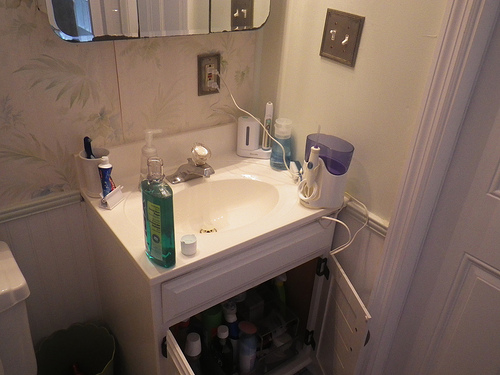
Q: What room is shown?
A: It is a bathroom.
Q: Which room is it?
A: It is a bathroom.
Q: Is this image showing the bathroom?
A: Yes, it is showing the bathroom.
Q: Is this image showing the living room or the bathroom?
A: It is showing the bathroom.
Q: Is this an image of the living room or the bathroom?
A: It is showing the bathroom.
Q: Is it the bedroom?
A: No, it is the bathroom.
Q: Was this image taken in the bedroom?
A: No, the picture was taken in the bathroom.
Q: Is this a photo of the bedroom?
A: No, the picture is showing the bathroom.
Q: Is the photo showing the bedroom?
A: No, the picture is showing the bathroom.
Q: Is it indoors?
A: Yes, it is indoors.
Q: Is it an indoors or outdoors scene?
A: It is indoors.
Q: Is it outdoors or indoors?
A: It is indoors.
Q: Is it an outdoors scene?
A: No, it is indoors.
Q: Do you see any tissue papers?
A: No, there are no tissue papers.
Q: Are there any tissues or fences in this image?
A: No, there are no tissues or fences.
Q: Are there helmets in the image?
A: No, there are no helmets.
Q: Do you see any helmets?
A: No, there are no helmets.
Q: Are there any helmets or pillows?
A: No, there are no helmets or pillows.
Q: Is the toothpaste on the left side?
A: Yes, the toothpaste is on the left of the image.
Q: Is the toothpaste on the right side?
A: No, the toothpaste is on the left of the image.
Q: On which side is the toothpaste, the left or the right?
A: The toothpaste is on the left of the image.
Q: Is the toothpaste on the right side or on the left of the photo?
A: The toothpaste is on the left of the image.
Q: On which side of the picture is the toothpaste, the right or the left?
A: The toothpaste is on the left of the image.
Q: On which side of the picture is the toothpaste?
A: The toothpaste is on the left of the image.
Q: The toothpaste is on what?
A: The toothpaste is on the sink.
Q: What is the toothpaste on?
A: The toothpaste is on the sink.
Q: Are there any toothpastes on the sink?
A: Yes, there is a toothpaste on the sink.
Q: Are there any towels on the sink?
A: No, there is a toothpaste on the sink.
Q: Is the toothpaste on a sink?
A: Yes, the toothpaste is on a sink.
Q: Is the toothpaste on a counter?
A: No, the toothpaste is on a sink.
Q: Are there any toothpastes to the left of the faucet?
A: Yes, there is a toothpaste to the left of the faucet.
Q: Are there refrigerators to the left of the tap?
A: No, there is a toothpaste to the left of the tap.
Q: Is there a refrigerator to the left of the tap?
A: No, there is a toothpaste to the left of the tap.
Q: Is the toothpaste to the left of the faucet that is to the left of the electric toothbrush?
A: Yes, the toothpaste is to the left of the tap.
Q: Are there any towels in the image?
A: No, there are no towels.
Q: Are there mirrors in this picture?
A: Yes, there is a mirror.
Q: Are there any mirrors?
A: Yes, there is a mirror.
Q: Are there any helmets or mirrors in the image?
A: Yes, there is a mirror.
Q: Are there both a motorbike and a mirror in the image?
A: No, there is a mirror but no motorcycles.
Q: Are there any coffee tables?
A: No, there are no coffee tables.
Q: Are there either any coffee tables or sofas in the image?
A: No, there are no coffee tables or sofas.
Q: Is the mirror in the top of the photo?
A: Yes, the mirror is in the top of the image.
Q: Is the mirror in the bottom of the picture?
A: No, the mirror is in the top of the image.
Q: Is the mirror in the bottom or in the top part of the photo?
A: The mirror is in the top of the image.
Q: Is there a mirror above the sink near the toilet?
A: Yes, there is a mirror above the sink.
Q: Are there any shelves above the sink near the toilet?
A: No, there is a mirror above the sink.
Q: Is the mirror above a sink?
A: Yes, the mirror is above a sink.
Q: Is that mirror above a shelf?
A: No, the mirror is above a sink.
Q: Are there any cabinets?
A: Yes, there is a cabinet.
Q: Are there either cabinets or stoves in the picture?
A: Yes, there is a cabinet.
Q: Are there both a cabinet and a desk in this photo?
A: No, there is a cabinet but no desks.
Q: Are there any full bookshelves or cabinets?
A: Yes, there is a full cabinet.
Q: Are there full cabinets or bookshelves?
A: Yes, there is a full cabinet.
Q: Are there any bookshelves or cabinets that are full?
A: Yes, the cabinet is full.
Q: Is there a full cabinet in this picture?
A: Yes, there is a full cabinet.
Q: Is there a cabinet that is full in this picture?
A: Yes, there is a full cabinet.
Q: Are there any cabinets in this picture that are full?
A: Yes, there is a cabinet that is full.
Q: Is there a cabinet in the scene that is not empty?
A: Yes, there is an full cabinet.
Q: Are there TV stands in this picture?
A: No, there are no TV stands.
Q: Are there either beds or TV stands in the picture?
A: No, there are no TV stands or beds.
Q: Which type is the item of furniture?
A: The piece of furniture is a cabinet.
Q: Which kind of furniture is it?
A: The piece of furniture is a cabinet.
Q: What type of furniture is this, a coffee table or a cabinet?
A: This is a cabinet.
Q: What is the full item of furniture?
A: The piece of furniture is a cabinet.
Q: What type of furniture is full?
A: The furniture is a cabinet.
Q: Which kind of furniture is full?
A: The furniture is a cabinet.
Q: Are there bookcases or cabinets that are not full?
A: No, there is a cabinet but it is full.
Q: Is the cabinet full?
A: Yes, the cabinet is full.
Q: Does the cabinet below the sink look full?
A: Yes, the cabinet is full.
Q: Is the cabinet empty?
A: No, the cabinet is full.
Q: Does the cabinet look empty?
A: No, the cabinet is full.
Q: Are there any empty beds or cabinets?
A: No, there is a cabinet but it is full.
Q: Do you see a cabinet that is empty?
A: No, there is a cabinet but it is full.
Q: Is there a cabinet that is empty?
A: No, there is a cabinet but it is full.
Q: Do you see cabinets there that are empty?
A: No, there is a cabinet but it is full.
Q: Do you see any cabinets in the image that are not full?
A: No, there is a cabinet but it is full.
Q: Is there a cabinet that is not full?
A: No, there is a cabinet but it is full.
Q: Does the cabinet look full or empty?
A: The cabinet is full.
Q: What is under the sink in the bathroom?
A: The cabinet is under the sink.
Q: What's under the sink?
A: The cabinet is under the sink.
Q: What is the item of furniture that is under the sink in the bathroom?
A: The piece of furniture is a cabinet.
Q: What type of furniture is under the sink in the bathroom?
A: The piece of furniture is a cabinet.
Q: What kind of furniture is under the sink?
A: The piece of furniture is a cabinet.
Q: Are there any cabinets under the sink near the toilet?
A: Yes, there is a cabinet under the sink.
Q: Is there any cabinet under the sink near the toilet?
A: Yes, there is a cabinet under the sink.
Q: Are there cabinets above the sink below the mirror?
A: No, the cabinet is under the sink.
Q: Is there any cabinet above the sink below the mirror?
A: No, the cabinet is under the sink.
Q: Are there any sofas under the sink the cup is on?
A: No, there is a cabinet under the sink.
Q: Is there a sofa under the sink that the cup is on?
A: No, there is a cabinet under the sink.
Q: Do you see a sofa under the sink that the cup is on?
A: No, there is a cabinet under the sink.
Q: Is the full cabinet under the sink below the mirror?
A: Yes, the cabinet is under the sink.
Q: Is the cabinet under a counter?
A: No, the cabinet is under the sink.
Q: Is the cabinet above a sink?
A: No, the cabinet is under a sink.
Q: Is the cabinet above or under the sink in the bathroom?
A: The cabinet is under the sink.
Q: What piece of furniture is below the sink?
A: The piece of furniture is a cabinet.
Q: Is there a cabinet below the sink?
A: Yes, there is a cabinet below the sink.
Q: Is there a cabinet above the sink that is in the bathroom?
A: No, the cabinet is below the sink.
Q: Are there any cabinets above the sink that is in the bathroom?
A: No, the cabinet is below the sink.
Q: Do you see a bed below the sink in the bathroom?
A: No, there is a cabinet below the sink.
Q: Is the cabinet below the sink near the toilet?
A: Yes, the cabinet is below the sink.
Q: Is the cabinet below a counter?
A: No, the cabinet is below the sink.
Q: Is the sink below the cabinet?
A: No, the cabinet is below the sink.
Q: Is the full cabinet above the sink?
A: No, the cabinet is below the sink.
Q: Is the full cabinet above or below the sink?
A: The cabinet is below the sink.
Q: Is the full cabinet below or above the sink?
A: The cabinet is below the sink.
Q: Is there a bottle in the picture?
A: Yes, there is a bottle.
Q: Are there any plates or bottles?
A: Yes, there is a bottle.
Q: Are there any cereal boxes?
A: No, there are no cereal boxes.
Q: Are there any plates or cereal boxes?
A: No, there are no cereal boxes or plates.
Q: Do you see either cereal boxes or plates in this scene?
A: No, there are no cereal boxes or plates.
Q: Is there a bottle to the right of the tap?
A: Yes, there is a bottle to the right of the tap.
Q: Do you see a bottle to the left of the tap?
A: No, the bottle is to the right of the tap.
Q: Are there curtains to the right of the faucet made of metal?
A: No, there is a bottle to the right of the faucet.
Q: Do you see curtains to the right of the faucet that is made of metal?
A: No, there is a bottle to the right of the faucet.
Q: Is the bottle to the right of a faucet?
A: Yes, the bottle is to the right of a faucet.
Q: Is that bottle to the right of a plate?
A: No, the bottle is to the right of a faucet.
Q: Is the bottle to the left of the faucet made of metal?
A: No, the bottle is to the right of the tap.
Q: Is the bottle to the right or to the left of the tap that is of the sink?
A: The bottle is to the right of the faucet.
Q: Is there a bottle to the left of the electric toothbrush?
A: Yes, there is a bottle to the left of the electric toothbrush.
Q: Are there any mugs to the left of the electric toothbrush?
A: No, there is a bottle to the left of the electric toothbrush.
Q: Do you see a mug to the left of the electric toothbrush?
A: No, there is a bottle to the left of the electric toothbrush.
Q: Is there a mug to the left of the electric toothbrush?
A: No, there is a bottle to the left of the electric toothbrush.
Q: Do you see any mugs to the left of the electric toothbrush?
A: No, there is a bottle to the left of the electric toothbrush.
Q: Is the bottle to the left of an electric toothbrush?
A: Yes, the bottle is to the left of an electric toothbrush.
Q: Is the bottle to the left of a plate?
A: No, the bottle is to the left of an electric toothbrush.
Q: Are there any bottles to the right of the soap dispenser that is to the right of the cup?
A: Yes, there is a bottle to the right of the soap dispenser.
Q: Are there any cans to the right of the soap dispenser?
A: No, there is a bottle to the right of the soap dispenser.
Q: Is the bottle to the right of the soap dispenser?
A: Yes, the bottle is to the right of the soap dispenser.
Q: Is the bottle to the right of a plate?
A: No, the bottle is to the right of the soap dispenser.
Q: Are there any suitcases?
A: No, there are no suitcases.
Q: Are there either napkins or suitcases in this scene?
A: No, there are no suitcases or napkins.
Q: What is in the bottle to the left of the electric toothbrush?
A: The liquid is in the bottle.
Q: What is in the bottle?
A: The liquid is in the bottle.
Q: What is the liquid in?
A: The liquid is in the bottle.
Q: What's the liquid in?
A: The liquid is in the bottle.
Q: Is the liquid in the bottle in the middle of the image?
A: Yes, the liquid is in the bottle.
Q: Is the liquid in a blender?
A: No, the liquid is in the bottle.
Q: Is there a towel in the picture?
A: No, there are no towels.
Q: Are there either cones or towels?
A: No, there are no towels or cones.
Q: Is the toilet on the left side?
A: Yes, the toilet is on the left of the image.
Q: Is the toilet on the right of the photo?
A: No, the toilet is on the left of the image.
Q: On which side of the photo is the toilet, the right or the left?
A: The toilet is on the left of the image.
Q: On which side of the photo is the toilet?
A: The toilet is on the left of the image.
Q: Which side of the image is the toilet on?
A: The toilet is on the left of the image.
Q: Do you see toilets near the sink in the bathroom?
A: Yes, there is a toilet near the sink.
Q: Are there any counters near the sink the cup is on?
A: No, there is a toilet near the sink.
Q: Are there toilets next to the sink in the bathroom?
A: Yes, there is a toilet next to the sink.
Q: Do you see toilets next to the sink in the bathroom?
A: Yes, there is a toilet next to the sink.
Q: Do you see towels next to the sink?
A: No, there is a toilet next to the sink.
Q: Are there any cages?
A: No, there are no cages.